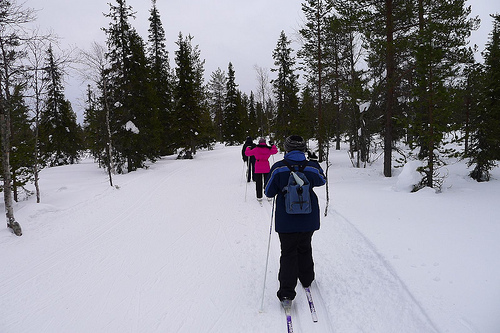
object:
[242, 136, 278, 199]
skier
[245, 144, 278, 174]
coat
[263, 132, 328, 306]
skier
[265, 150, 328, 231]
coat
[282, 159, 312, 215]
backpack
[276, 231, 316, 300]
pants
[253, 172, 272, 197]
pants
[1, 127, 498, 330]
ground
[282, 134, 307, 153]
cap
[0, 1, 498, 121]
sky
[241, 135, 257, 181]
skier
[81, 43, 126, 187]
tree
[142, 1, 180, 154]
tree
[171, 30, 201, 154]
tree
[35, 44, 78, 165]
tree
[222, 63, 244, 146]
tree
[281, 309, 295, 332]
ski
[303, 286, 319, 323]
ski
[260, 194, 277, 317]
pole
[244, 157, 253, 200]
pole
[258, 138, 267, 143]
cap